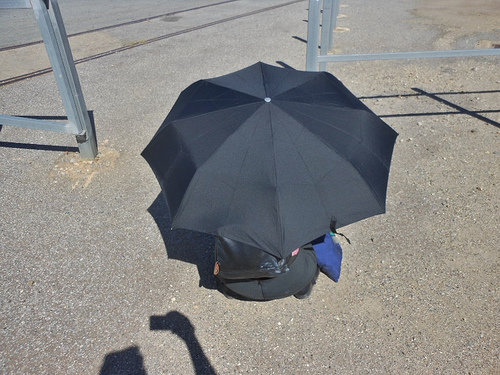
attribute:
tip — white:
[239, 83, 292, 118]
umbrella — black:
[189, 75, 329, 187]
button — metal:
[252, 80, 278, 116]